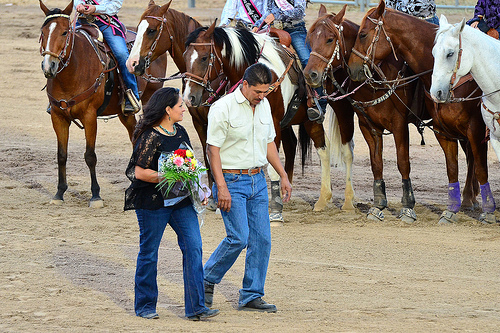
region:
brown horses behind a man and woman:
[1, 2, 499, 332]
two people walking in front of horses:
[1, 2, 499, 332]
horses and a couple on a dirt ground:
[2, 2, 495, 329]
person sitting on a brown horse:
[34, 0, 167, 210]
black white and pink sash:
[240, 0, 270, 25]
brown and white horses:
[301, 0, 493, 228]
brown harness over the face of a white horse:
[425, 11, 499, 162]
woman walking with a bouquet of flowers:
[121, 84, 223, 319]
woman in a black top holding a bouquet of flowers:
[118, 83, 227, 321]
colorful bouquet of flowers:
[148, 144, 215, 211]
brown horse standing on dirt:
[21, 1, 137, 208]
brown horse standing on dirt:
[120, 6, 211, 94]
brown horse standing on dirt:
[175, 21, 260, 93]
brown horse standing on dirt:
[301, 12, 419, 220]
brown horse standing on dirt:
[351, 3, 498, 214]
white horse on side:
[424, 19, 498, 121]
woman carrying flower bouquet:
[100, 82, 214, 227]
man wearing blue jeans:
[198, 161, 296, 301]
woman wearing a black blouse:
[114, 131, 205, 209]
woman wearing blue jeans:
[120, 185, 212, 330]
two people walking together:
[76, 32, 343, 317]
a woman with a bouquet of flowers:
[80, 57, 244, 302]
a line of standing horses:
[26, 7, 498, 228]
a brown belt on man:
[216, 148, 287, 198]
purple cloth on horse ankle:
[421, 154, 496, 231]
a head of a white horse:
[410, 21, 499, 143]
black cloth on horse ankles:
[352, 162, 434, 232]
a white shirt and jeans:
[203, 84, 300, 308]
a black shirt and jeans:
[108, 119, 233, 302]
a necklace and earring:
[147, 112, 187, 140]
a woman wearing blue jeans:
[121, 86, 218, 320]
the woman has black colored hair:
[124, 84, 220, 321]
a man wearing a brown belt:
[201, 63, 291, 313]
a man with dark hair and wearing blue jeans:
[204, 63, 291, 312]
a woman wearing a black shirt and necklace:
[123, 85, 213, 317]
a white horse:
[428, 13, 498, 166]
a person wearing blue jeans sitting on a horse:
[36, 1, 170, 210]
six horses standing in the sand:
[35, 0, 499, 209]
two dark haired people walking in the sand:
[124, 63, 295, 320]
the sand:
[368, 242, 480, 278]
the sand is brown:
[354, 269, 416, 309]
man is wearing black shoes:
[256, 296, 277, 314]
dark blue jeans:
[135, 227, 157, 278]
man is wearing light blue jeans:
[223, 214, 247, 252]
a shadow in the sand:
[63, 244, 103, 284]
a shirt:
[215, 109, 272, 161]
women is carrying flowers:
[173, 149, 198, 171]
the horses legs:
[50, 128, 109, 212]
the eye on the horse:
[445, 49, 459, 59]